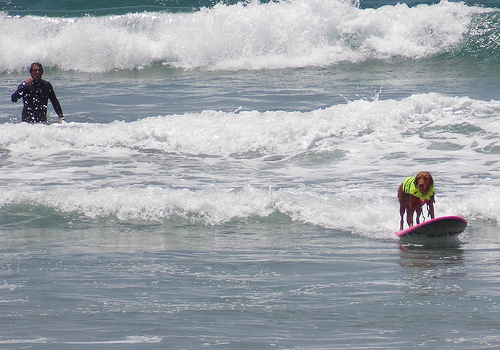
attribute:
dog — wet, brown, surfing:
[394, 171, 440, 222]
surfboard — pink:
[400, 212, 472, 241]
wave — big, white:
[6, 6, 499, 74]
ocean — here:
[6, 8, 499, 239]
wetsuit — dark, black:
[25, 95, 52, 115]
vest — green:
[400, 177, 432, 196]